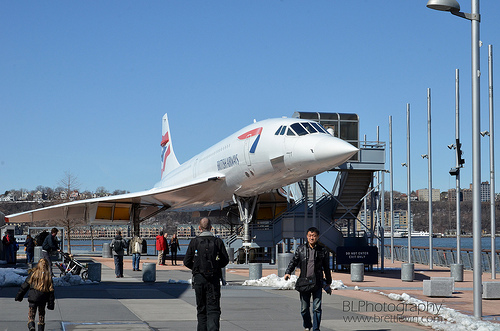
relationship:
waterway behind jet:
[61, 236, 498, 269] [20, 53, 358, 265]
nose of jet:
[317, 130, 362, 167] [2, 109, 358, 257]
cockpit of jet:
[287, 122, 326, 137] [2, 109, 358, 257]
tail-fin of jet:
[156, 110, 181, 168] [5, 112, 364, 227]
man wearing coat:
[181, 216, 230, 329] [177, 235, 236, 278]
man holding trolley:
[180, 215, 229, 331] [56, 247, 103, 285]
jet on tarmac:
[5, 112, 364, 227] [6, 249, 479, 308]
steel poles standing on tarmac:
[427, 87, 433, 271] [0, 253, 500, 331]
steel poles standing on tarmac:
[454, 67, 461, 263] [0, 253, 500, 331]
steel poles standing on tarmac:
[486, 43, 496, 279] [0, 253, 500, 331]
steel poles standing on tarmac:
[405, 101, 412, 261] [0, 253, 500, 331]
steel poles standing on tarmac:
[387, 112, 395, 262] [0, 253, 500, 331]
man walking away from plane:
[180, 215, 229, 331] [6, 99, 383, 261]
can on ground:
[83, 253, 105, 280] [8, 247, 481, 328]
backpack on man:
[190, 230, 223, 290] [181, 216, 230, 329]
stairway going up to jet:
[292, 173, 320, 209] [2, 111, 364, 225]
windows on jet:
[275, 116, 330, 134] [2, 111, 364, 225]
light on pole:
[448, 162, 460, 182] [427, 0, 481, 318]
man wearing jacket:
[180, 215, 229, 331] [266, 214, 353, 316]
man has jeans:
[180, 215, 229, 331] [302, 289, 342, 311]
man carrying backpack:
[181, 216, 230, 329] [192, 236, 219, 277]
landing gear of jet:
[233, 195, 257, 262] [2, 109, 358, 257]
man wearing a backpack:
[181, 216, 230, 329] [190, 234, 227, 289]